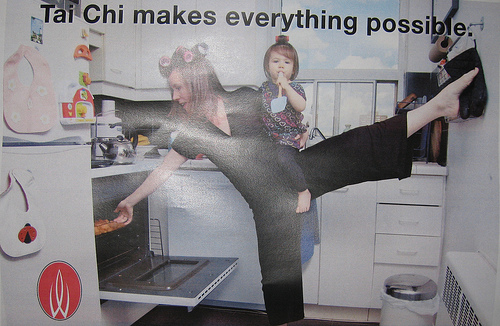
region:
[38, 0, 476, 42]
black letters on picture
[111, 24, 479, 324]
the woman is pulling something from oven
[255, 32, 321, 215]
little girl holding kitchen utensil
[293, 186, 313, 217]
little girl is barefoot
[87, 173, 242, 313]
oven door is open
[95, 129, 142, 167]
tea kettle on stove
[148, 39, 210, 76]
hair rollers in woman's hair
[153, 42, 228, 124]
woman's hair is blonde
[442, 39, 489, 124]
woman's foot on oven mit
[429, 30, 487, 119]
a woman kicking a black oven mitt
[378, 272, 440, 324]
a silver trash can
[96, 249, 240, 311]
an open overn door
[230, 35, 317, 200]
a woman holding a young child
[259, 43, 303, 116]
a child holding a rubber spatula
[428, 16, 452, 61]
a paper towel roll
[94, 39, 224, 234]
a woman reaching in the oven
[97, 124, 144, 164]
a silver tea pot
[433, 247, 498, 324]
a white radiator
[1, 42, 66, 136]
a baby's bib hanging on a refrigerator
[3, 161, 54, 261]
a baby's bib hanging on a refrigerator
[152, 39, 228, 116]
a woman with curlers in her hair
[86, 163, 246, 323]
the open door of an oven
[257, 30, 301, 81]
the head of a little girl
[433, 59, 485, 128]
the foot of a woman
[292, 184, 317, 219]
the foot of a little girl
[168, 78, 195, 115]
the face of a woman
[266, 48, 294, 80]
the face of a little girl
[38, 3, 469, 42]
black lettering on advertisement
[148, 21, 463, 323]
woman holding a child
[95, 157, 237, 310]
oven with open door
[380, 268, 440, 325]
white trashcan with silver lid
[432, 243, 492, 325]
white vent on the wall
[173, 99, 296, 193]
black shirt woman is wearing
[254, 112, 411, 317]
black pants woman is wearing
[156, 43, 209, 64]
curlers in the woman's hair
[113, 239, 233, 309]
open door of the oven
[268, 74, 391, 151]
windows over the sink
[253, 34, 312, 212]
little girl with no shoes on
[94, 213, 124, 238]
food in the oven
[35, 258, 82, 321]
round red sticker on the fridge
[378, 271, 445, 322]
white and silver trash can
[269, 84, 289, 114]
spatula in girl's mouth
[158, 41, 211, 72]
pink curlers in woman's hair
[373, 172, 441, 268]
white drawers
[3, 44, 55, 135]
pink floral bib on the fridge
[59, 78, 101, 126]
magnetic barn on the fridge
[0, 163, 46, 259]
white ladybug bib on the fridge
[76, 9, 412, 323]
a woman grabbing a pizza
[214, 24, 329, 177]
a child on the woman's hip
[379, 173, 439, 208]
a white cabinet drawer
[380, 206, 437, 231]
a white cabinet drawer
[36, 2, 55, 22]
black print style letter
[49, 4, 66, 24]
black print style letter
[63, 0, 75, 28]
black print style letter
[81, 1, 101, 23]
black print style letter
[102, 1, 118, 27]
black print style letter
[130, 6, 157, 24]
black print style letter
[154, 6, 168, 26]
black print style letter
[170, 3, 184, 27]
black print style letter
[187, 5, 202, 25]
black print style letter